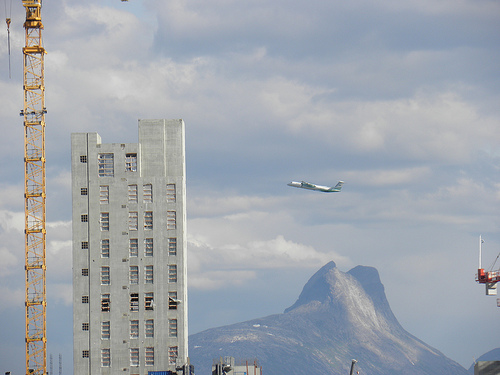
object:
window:
[80, 348, 90, 363]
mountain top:
[303, 258, 385, 317]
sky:
[0, 0, 499, 375]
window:
[98, 172, 115, 178]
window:
[78, 155, 89, 164]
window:
[80, 187, 89, 197]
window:
[80, 213, 88, 222]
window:
[124, 152, 139, 158]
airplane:
[282, 180, 344, 194]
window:
[81, 322, 90, 331]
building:
[67, 118, 189, 372]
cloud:
[0, 0, 499, 374]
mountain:
[188, 260, 468, 374]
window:
[101, 238, 111, 245]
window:
[80, 215, 87, 222]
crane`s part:
[474, 234, 500, 307]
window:
[79, 187, 90, 196]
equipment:
[20, 0, 51, 375]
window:
[166, 305, 179, 311]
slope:
[270, 269, 466, 375]